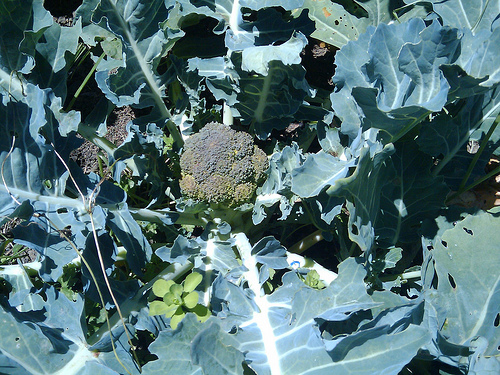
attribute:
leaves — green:
[106, 42, 288, 108]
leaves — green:
[0, 0, 498, 374]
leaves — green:
[332, 150, 385, 270]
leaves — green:
[353, 17, 453, 136]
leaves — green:
[216, 229, 424, 374]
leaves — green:
[93, 4, 180, 104]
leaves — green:
[234, 40, 307, 135]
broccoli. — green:
[155, 88, 272, 231]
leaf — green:
[330, 2, 462, 125]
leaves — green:
[0, 280, 117, 373]